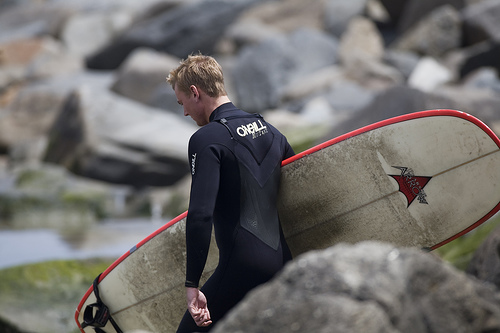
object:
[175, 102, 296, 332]
swimsuit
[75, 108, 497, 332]
surfboard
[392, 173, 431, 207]
arrow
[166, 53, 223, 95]
hair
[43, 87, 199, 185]
rock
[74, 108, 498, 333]
frame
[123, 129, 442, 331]
dirt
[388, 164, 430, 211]
logo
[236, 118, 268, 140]
logo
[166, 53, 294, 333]
surfer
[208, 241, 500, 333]
boulder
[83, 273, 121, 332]
strap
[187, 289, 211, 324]
left hand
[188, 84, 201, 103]
ear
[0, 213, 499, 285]
grass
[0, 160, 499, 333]
ground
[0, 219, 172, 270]
water